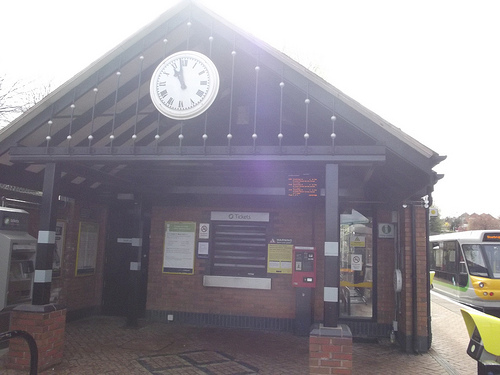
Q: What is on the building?
A: Clock.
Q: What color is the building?
A: Brown.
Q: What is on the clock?
A: Numbers.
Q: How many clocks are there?
A: One.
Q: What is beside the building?
A: Bus.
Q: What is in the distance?
A: Trees.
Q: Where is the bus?
A: Beside building.